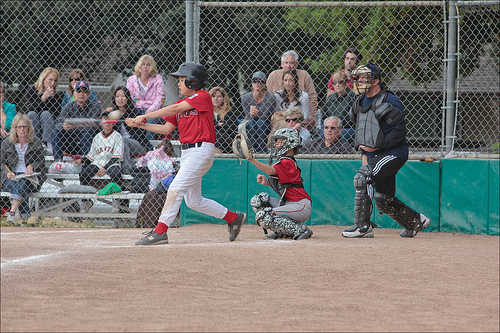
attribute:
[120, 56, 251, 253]
boy — batter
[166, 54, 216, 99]
helmet — black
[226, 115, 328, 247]
boy — catcher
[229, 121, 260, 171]
glove — leather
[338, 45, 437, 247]
man — umpire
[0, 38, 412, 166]
people — sitting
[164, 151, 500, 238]
barrier — turquoise, padded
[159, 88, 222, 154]
jersey — red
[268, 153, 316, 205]
jersey — red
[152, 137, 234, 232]
pants — white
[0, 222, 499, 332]
ground — dry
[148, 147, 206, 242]
leg — straight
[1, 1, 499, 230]
fence — metal, gray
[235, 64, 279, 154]
woman — sitting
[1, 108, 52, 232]
woman — blonde, sitting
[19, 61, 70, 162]
woman — blonde, sitting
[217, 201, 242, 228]
sock — red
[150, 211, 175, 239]
sock — red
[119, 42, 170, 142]
woman — blonde, sitting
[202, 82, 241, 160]
woman — sitting